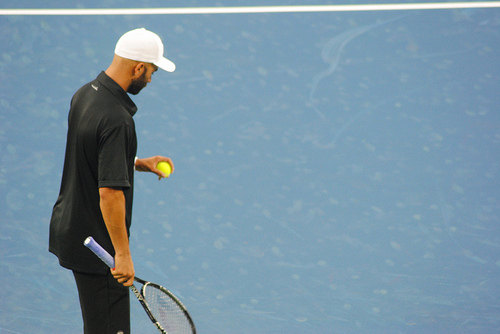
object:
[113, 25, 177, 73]
hat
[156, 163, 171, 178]
ball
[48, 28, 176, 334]
man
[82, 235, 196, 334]
racket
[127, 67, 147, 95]
beard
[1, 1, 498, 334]
background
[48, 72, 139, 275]
shirt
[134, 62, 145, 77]
ear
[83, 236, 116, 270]
handle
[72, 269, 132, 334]
tennis shorts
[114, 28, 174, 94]
head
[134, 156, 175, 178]
hand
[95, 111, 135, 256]
arm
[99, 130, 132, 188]
sleeve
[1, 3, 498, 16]
line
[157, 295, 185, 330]
corporate logo